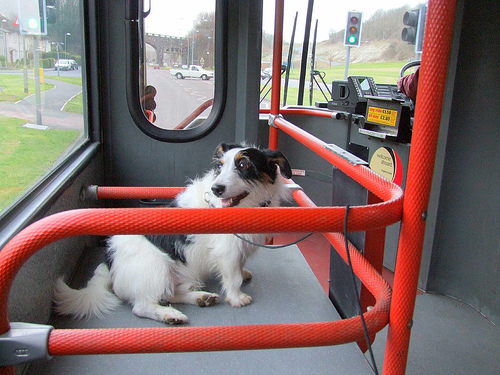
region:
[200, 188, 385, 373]
dog's leash wrapped over handrail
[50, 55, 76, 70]
two cars parked inexplicably very close together seen from left bus window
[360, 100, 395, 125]
two yellow stickers explaining bus fares in british pounds on bus farebox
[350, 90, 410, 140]
metal bus farebox beside driver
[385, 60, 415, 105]
bus driver drives on right side of bus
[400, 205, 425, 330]
two bolts that fasten post to handrail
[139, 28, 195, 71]
odd looking bridge ahead, seen from left front window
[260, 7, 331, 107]
two bus windshield wipers standing vertically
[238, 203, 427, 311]
floor of bus beside driver is red & matches bus handrails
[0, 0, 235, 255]
black rubber encircling bus windows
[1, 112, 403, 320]
orange metal bus railing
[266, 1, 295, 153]
orange metal bus railing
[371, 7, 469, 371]
orange metal bus railing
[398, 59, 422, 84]
black steering wheel of bus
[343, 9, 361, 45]
traffic light with green light on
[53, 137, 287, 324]
black white and brown small dog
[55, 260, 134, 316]
long white fluffy tail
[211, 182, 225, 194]
black dog nose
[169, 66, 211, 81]
long white pickup truck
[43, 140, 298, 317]
Black and white dog sitting in bus.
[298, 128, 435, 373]
Orange rails inside bus.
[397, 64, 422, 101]
Arm of person driving bus.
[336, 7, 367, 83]
Traffic light on green.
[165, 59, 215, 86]
White truck turning corner.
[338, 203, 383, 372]
Black leash round dog.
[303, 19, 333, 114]
Windshield wiper on front window of bus.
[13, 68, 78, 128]
Winding sidewalk next to road.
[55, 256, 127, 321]
Dog's long white tail.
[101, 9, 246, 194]
Door leading into bus.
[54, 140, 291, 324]
the dog is on the bus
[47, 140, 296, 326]
the dog is brown and white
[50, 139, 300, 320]
the dog looks out the window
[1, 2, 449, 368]
the bars are red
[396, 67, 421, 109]
the driver drives the bus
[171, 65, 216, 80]
a truck makes a turn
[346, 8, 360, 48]
the light is green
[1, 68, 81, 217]
the grass is green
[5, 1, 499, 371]
the bus is gray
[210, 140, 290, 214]
the dog looks happy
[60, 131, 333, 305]
dog sitting on seat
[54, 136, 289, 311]
small black and white dog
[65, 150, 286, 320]
small long hair dog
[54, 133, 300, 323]
dog with long tail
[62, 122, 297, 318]
pretty dog with black nose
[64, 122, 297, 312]
small dog with black ears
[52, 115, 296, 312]
little dog with white paws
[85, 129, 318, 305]
small dog with mouth open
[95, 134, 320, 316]
dog sitting on seat on bus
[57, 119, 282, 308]
small dog with brown eyes